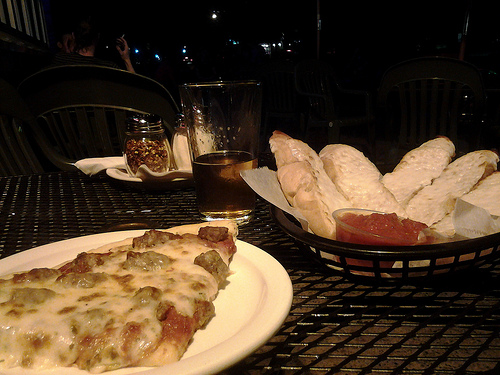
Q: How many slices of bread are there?
A: Five.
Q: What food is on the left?
A: Pizza.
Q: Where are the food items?
A: On the table.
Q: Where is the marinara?
A: In the basket.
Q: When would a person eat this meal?
A: Dinner.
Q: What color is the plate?
A: White.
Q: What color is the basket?
A: Black.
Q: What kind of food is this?
A: Italian.